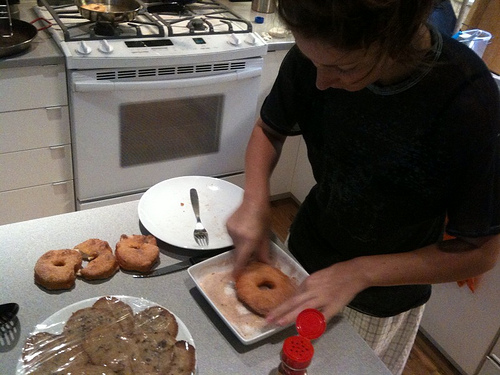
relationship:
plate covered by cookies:
[17, 295, 200, 375] [22, 297, 195, 375]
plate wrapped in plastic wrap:
[17, 295, 200, 375] [17, 295, 200, 374]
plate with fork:
[137, 176, 245, 249] [188, 188, 207, 240]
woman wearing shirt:
[226, 0, 500, 374] [259, 23, 498, 316]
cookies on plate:
[22, 297, 195, 375] [17, 295, 200, 375]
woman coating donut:
[226, 0, 500, 374] [236, 262, 293, 315]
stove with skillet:
[34, 0, 267, 212] [76, 1, 181, 26]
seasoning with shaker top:
[277, 308, 326, 374] [280, 309, 326, 370]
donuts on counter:
[35, 233, 159, 292] [1, 200, 393, 374]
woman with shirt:
[226, 0, 500, 374] [259, 23, 498, 316]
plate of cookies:
[17, 295, 200, 375] [22, 297, 195, 375]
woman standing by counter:
[226, 0, 500, 374] [1, 200, 393, 374]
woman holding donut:
[226, 0, 500, 374] [236, 262, 293, 315]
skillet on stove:
[76, 1, 181, 26] [34, 0, 267, 212]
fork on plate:
[188, 188, 207, 240] [137, 176, 245, 249]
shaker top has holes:
[280, 309, 326, 370] [290, 339, 309, 357]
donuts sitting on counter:
[35, 233, 159, 292] [1, 200, 393, 374]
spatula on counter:
[0, 302, 19, 328] [1, 200, 393, 374]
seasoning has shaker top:
[277, 308, 326, 374] [280, 309, 326, 370]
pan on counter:
[0, 16, 53, 60] [0, 0, 66, 69]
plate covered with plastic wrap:
[17, 295, 200, 375] [17, 295, 200, 374]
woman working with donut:
[226, 0, 500, 374] [236, 262, 293, 315]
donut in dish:
[236, 262, 293, 315] [187, 239, 312, 345]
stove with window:
[34, 0, 267, 212] [118, 92, 226, 168]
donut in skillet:
[82, 3, 107, 13] [76, 1, 181, 26]